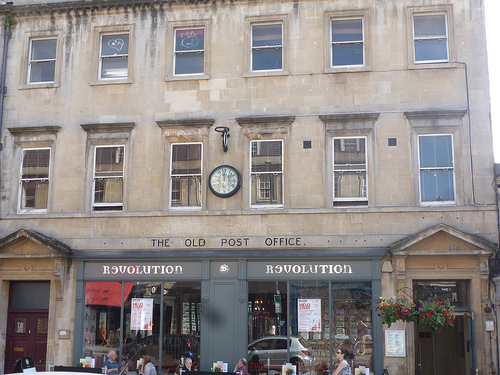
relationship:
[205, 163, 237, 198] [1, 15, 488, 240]
clock attached to building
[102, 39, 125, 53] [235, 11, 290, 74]
heart on top of window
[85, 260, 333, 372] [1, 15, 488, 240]
entries to building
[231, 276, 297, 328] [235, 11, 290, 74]
reflection on window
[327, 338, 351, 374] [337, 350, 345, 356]
woman wearing sunglasses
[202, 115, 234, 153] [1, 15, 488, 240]
pipe attached to building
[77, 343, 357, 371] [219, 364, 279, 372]
people sitting at tables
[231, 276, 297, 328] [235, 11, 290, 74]
reflection on top of window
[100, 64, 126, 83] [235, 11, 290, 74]
sign attached to window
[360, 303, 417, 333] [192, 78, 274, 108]
plants hanging off wall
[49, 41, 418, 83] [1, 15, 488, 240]
windows attached to building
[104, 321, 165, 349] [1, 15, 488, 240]
door attached to building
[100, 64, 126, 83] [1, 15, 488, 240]
sign attached to building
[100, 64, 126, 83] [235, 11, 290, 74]
sign on front of window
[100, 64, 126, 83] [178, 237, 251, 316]
sign attached to store front